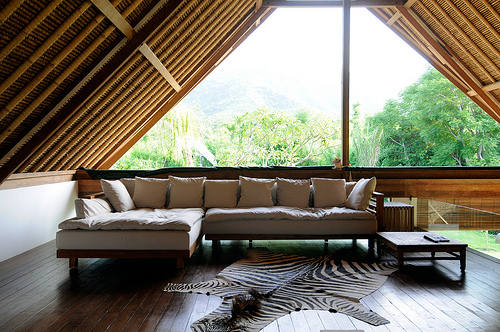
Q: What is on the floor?
A: Zebra rug.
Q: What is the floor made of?
A: Wood.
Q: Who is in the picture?
A: No one.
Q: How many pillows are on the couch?
A: Eight.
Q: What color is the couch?
A: White.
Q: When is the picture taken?
A: Day time.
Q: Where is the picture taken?
A: Loft.